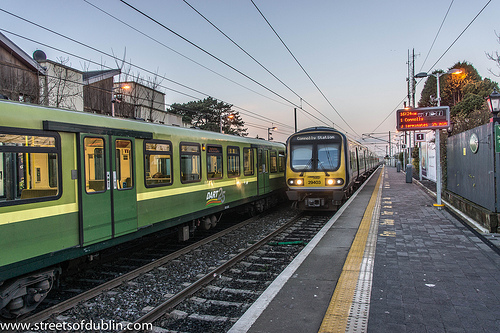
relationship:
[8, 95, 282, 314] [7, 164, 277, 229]
train with a stripe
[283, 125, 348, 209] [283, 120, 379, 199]
front of train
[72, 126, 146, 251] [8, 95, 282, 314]
doors to enter and exit train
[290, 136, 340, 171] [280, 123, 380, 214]
windshield of train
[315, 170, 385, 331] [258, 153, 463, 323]
stripe on sidewalk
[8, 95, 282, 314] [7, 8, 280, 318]
train to left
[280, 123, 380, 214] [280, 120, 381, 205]
train to right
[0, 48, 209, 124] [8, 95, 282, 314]
houses behind train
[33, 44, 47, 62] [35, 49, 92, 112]
dish above house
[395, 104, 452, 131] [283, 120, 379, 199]
board next to train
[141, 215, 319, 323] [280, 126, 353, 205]
tracks in front of train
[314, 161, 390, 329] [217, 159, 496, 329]
line on platform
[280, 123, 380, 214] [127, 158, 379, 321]
train on track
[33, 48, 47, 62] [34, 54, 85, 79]
dish on roof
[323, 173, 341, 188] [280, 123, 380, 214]
head light on train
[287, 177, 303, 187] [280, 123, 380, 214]
head light on train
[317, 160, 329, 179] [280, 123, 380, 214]
wiper on train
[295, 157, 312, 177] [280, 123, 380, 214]
wiper on train